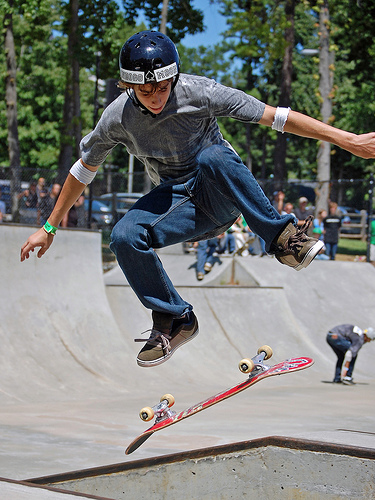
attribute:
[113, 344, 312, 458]
skateboard — red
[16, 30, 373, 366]
boy — doing a trick, young, performing trick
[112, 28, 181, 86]
helmet — blue, dark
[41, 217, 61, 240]
wristband — green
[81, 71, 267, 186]
shirt — gray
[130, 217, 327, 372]
shoes — brown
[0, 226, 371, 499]
ramp — made of concrete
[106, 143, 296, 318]
pants — blue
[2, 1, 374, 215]
trees — tall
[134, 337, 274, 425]
skateboard's wheels — tan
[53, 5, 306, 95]
sky — clear